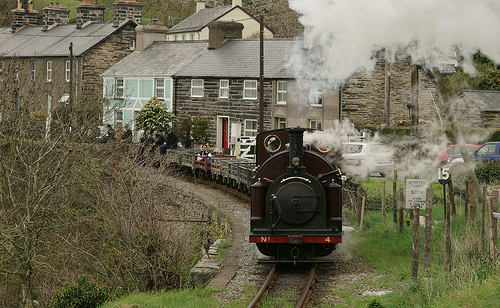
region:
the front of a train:
[244, 118, 341, 260]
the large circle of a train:
[270, 175, 315, 223]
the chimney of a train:
[277, 121, 324, 161]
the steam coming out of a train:
[285, 12, 352, 103]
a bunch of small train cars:
[170, 141, 272, 191]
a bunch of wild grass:
[78, 208, 123, 263]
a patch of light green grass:
[112, 281, 184, 306]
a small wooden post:
[390, 198, 438, 268]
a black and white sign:
[397, 173, 431, 218]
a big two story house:
[171, 28, 351, 146]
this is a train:
[162, 129, 341, 262]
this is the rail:
[246, 262, 321, 306]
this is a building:
[2, 0, 112, 137]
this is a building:
[106, 2, 344, 154]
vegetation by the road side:
[4, 76, 180, 293]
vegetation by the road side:
[398, 265, 498, 303]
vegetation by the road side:
[101, 283, 216, 305]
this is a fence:
[357, 163, 497, 304]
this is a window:
[187, 76, 203, 98]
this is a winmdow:
[217, 77, 230, 98]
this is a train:
[253, 93, 355, 239]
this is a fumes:
[289, 51, 356, 143]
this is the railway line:
[253, 267, 303, 302]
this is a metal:
[299, 286, 314, 304]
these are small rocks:
[238, 263, 255, 274]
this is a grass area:
[149, 285, 171, 300]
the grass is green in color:
[365, 240, 394, 286]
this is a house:
[141, 25, 244, 111]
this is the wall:
[171, 91, 216, 126]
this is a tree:
[136, 93, 176, 148]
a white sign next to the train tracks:
[403, 173, 424, 281]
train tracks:
[243, 269, 324, 303]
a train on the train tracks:
[233, 126, 352, 270]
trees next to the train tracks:
[0, 128, 185, 303]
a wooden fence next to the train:
[361, 178, 494, 266]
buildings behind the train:
[11, 18, 428, 140]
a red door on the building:
[218, 117, 228, 150]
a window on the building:
[188, 80, 205, 100]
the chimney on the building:
[111, 2, 143, 22]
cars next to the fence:
[430, 135, 491, 165]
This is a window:
[184, 75, 207, 107]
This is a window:
[215, 75, 234, 105]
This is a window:
[237, 73, 262, 101]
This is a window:
[266, 75, 298, 102]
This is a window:
[239, 115, 259, 139]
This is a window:
[109, 103, 128, 143]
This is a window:
[104, 75, 119, 105]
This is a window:
[120, 70, 140, 97]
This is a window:
[136, 78, 157, 100]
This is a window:
[42, 58, 57, 89]